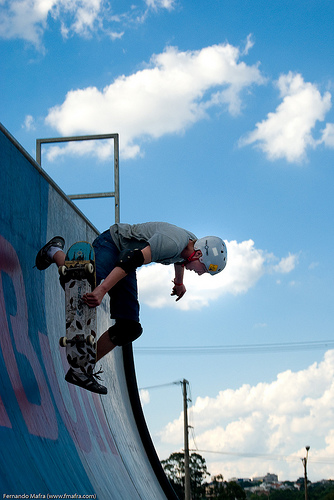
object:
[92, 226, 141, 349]
jeans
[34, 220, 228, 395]
skater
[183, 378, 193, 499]
pole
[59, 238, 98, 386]
skateboard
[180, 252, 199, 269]
strap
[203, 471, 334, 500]
cityscape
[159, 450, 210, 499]
tree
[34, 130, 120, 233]
handbar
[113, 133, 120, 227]
pole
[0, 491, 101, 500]
website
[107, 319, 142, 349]
pad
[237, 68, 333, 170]
cloud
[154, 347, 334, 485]
cloud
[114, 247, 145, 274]
elbow pad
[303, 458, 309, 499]
post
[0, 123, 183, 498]
ramp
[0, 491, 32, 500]
name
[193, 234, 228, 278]
helmet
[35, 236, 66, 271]
shoes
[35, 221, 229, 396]
person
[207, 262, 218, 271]
sticker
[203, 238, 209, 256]
sticker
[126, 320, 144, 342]
knee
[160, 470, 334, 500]
horizon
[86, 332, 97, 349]
wheels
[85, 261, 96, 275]
wheels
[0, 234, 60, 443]
letter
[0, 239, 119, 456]
lettering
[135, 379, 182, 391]
wires